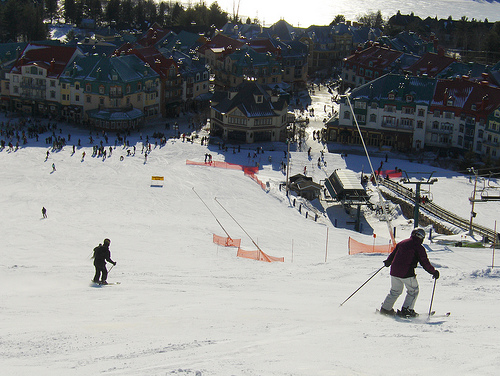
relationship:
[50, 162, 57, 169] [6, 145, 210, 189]
skiers at hill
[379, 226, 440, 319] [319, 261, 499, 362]
person on slope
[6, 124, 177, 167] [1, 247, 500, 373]
skiers on ski slope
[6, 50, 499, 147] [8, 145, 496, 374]
buildings by slopes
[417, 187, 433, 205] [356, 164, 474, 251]
chair lift by ski slope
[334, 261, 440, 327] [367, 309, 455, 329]
poles near skis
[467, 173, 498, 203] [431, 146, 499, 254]
chair lift in air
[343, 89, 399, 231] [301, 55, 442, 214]
wires up in air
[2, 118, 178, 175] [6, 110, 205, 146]
people on shadow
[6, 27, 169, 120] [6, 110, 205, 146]
building has shadow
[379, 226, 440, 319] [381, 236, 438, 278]
person wears sweater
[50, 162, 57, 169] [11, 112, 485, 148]
skiers on back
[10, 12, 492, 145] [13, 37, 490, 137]
cabins on back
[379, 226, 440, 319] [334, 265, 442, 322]
person holds ski poles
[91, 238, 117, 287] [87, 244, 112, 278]
person wears suit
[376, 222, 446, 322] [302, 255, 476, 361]
person on snow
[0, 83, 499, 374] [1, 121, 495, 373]
snow on ground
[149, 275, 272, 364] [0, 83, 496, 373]
snow covering ground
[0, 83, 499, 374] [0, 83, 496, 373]
snow covering ground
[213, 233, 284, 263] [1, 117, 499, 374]
barrier in snow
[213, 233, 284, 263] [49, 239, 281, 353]
barrier in snow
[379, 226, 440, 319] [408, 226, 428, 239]
person with helmet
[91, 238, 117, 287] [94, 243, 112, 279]
person in clothes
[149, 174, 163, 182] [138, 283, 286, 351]
flag sitting in snow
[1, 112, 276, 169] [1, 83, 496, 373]
people on bottom ski slope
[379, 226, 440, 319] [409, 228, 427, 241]
person wearing helmet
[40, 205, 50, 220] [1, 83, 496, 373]
person standing at bottom ski slope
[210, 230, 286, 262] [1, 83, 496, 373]
barriers on ski slope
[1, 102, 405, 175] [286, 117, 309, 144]
crowd standing near ski lift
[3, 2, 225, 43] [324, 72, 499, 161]
trees behind buildings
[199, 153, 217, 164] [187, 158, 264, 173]
people standing behind barrier